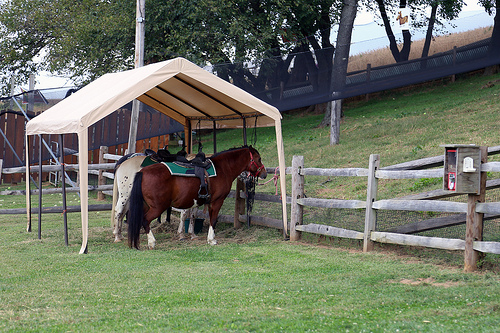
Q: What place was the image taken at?
A: It was taken at the pasture.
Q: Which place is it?
A: It is a pasture.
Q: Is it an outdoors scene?
A: Yes, it is outdoors.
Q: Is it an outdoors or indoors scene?
A: It is outdoors.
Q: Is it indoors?
A: No, it is outdoors.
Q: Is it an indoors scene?
A: No, it is outdoors.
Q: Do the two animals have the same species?
A: Yes, all the animals are horses.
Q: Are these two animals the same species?
A: Yes, all the animals are horses.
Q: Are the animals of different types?
A: No, all the animals are horses.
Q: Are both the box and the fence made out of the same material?
A: Yes, both the box and the fence are made of wood.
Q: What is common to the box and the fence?
A: The material, both the box and the fence are wooden.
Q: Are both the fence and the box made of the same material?
A: Yes, both the fence and the box are made of wood.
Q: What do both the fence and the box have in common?
A: The material, both the fence and the box are wooden.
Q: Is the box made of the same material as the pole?
A: No, the box is made of wood and the pole is made of metal.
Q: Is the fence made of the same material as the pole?
A: No, the fence is made of wood and the pole is made of metal.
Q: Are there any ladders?
A: No, there are no ladders.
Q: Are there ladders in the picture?
A: No, there are no ladders.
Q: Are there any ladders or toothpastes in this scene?
A: No, there are no ladders or toothpastes.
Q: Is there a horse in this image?
A: Yes, there is a horse.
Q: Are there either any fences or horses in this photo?
A: Yes, there is a horse.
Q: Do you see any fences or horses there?
A: Yes, there is a horse.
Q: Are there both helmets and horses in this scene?
A: No, there is a horse but no helmets.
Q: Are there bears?
A: No, there are no bears.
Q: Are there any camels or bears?
A: No, there are no bears or camels.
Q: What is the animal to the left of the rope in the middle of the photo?
A: The animal is a horse.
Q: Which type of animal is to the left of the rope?
A: The animal is a horse.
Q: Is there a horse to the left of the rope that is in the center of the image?
A: Yes, there is a horse to the left of the rope.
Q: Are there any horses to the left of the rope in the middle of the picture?
A: Yes, there is a horse to the left of the rope.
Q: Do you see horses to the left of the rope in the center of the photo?
A: Yes, there is a horse to the left of the rope.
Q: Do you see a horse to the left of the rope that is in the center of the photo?
A: Yes, there is a horse to the left of the rope.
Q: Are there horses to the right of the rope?
A: No, the horse is to the left of the rope.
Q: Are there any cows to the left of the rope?
A: No, there is a horse to the left of the rope.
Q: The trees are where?
A: The trees are on the hill.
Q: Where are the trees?
A: The trees are on the hill.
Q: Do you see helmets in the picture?
A: No, there are no helmets.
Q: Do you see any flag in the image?
A: No, there are no flags.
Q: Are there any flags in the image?
A: No, there are no flags.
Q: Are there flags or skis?
A: No, there are no flags or skis.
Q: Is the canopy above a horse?
A: Yes, the canopy is above a horse.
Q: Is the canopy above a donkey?
A: No, the canopy is above a horse.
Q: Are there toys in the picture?
A: No, there are no toys.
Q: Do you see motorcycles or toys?
A: No, there are no toys or motorcycles.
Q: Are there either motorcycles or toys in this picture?
A: No, there are no toys or motorcycles.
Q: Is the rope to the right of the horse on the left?
A: Yes, the rope is to the right of the horse.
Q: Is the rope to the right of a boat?
A: No, the rope is to the right of the horse.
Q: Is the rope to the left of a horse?
A: No, the rope is to the right of a horse.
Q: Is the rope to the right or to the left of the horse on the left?
A: The rope is to the right of the horse.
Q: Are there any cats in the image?
A: No, there are no cats.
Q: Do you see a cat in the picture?
A: No, there are no cats.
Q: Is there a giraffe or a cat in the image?
A: No, there are no cats or giraffes.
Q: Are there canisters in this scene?
A: No, there are no canisters.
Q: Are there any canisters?
A: No, there are no canisters.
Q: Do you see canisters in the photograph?
A: No, there are no canisters.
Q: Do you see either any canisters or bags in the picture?
A: No, there are no canisters or bags.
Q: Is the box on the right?
A: Yes, the box is on the right of the image.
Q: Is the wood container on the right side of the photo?
A: Yes, the box is on the right of the image.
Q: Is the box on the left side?
A: No, the box is on the right of the image.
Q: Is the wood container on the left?
A: No, the box is on the right of the image.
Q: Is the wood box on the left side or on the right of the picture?
A: The box is on the right of the image.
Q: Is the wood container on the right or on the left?
A: The box is on the right of the image.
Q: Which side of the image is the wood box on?
A: The box is on the right of the image.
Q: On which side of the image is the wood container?
A: The box is on the right of the image.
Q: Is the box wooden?
A: Yes, the box is wooden.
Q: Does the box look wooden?
A: Yes, the box is wooden.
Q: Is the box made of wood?
A: Yes, the box is made of wood.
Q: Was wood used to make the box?
A: Yes, the box is made of wood.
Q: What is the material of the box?
A: The box is made of wood.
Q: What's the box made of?
A: The box is made of wood.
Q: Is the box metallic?
A: No, the box is wooden.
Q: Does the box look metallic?
A: No, the box is wooden.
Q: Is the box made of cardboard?
A: No, the box is made of wood.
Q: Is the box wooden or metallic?
A: The box is wooden.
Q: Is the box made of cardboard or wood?
A: The box is made of wood.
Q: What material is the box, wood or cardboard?
A: The box is made of wood.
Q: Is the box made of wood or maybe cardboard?
A: The box is made of wood.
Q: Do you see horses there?
A: Yes, there is a horse.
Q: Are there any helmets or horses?
A: Yes, there is a horse.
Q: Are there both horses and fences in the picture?
A: Yes, there are both a horse and a fence.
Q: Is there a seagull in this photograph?
A: No, there are no seagulls.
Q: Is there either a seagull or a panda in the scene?
A: No, there are no seagulls or pandas.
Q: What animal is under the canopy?
A: The horse is under the canopy.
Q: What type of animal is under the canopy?
A: The animal is a horse.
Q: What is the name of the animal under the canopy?
A: The animal is a horse.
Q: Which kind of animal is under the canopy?
A: The animal is a horse.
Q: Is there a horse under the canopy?
A: Yes, there is a horse under the canopy.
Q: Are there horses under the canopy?
A: Yes, there is a horse under the canopy.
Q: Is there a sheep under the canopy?
A: No, there is a horse under the canopy.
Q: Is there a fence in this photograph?
A: Yes, there is a fence.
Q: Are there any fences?
A: Yes, there is a fence.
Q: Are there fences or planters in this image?
A: Yes, there is a fence.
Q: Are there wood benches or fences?
A: Yes, there is a wood fence.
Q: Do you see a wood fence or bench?
A: Yes, there is a wood fence.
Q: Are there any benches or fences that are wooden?
A: Yes, the fence is wooden.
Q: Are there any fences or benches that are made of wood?
A: Yes, the fence is made of wood.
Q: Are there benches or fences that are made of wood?
A: Yes, the fence is made of wood.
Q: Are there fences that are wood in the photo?
A: Yes, there is a wood fence.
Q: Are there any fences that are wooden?
A: Yes, there is a fence that is wooden.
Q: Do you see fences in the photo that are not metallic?
A: Yes, there is a wooden fence.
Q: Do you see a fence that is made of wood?
A: Yes, there is a fence that is made of wood.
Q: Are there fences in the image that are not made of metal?
A: Yes, there is a fence that is made of wood.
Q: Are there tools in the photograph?
A: No, there are no tools.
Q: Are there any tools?
A: No, there are no tools.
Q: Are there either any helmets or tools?
A: No, there are no tools or helmets.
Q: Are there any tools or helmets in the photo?
A: No, there are no tools or helmets.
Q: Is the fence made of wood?
A: Yes, the fence is made of wood.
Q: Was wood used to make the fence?
A: Yes, the fence is made of wood.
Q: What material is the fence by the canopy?
A: The fence is made of wood.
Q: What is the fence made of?
A: The fence is made of wood.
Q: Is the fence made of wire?
A: No, the fence is made of wood.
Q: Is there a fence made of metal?
A: No, there is a fence but it is made of wood.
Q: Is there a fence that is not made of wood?
A: No, there is a fence but it is made of wood.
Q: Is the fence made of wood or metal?
A: The fence is made of wood.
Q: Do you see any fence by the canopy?
A: Yes, there is a fence by the canopy.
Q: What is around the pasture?
A: The fence is around the pasture.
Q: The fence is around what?
A: The fence is around the pasture.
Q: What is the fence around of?
A: The fence is around the pasture.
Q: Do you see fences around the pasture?
A: Yes, there is a fence around the pasture.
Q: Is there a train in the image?
A: No, there are no trains.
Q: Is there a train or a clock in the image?
A: No, there are no trains or clocks.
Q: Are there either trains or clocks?
A: No, there are no trains or clocks.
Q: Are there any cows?
A: No, there are no cows.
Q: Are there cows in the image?
A: No, there are no cows.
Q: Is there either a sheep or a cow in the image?
A: No, there are no cows or sheep.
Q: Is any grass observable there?
A: Yes, there is grass.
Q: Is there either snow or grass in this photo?
A: Yes, there is grass.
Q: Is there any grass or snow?
A: Yes, there is grass.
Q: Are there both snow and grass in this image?
A: No, there is grass but no snow.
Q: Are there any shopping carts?
A: No, there are no shopping carts.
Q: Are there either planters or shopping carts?
A: No, there are no shopping carts or planters.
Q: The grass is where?
A: The grass is in the pasture.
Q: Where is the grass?
A: The grass is in the pasture.